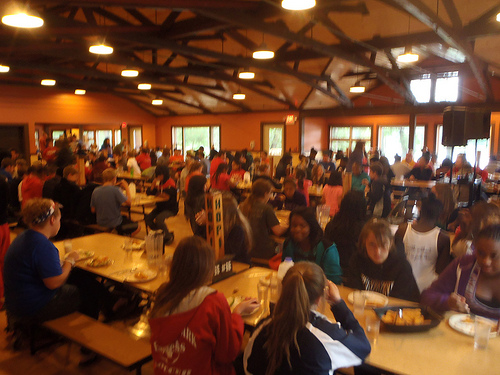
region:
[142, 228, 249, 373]
girl wearing a red hoodie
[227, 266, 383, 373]
girl wearing a blue and white jacket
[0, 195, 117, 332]
boy wearing blue shirt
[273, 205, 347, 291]
girl wearing a teal jacket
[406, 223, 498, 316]
girl wearing a purple jacket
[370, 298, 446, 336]
lunch on the table top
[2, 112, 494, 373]
this is a cafeteria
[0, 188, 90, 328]
boy wearing a headband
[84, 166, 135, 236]
boy wearing a blue shirt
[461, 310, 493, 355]
a cup on the table top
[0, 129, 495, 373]
the cafeteria filled with people eating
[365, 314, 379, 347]
the cup on the table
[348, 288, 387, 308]
the plate on the table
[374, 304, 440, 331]
the big bowl on the table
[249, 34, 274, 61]
the light hanging from the ceiling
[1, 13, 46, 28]
the tree in the distance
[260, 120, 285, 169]
the door to the room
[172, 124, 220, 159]
the window near the door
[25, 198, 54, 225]
the fabric in the girl's hair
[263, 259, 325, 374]
the girl's hair in a ponytail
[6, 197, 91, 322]
a girl in a blue shirt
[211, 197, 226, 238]
the word hop in black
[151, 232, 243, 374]
a girl wearing a red and white hoodie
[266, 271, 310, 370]
a girls long brown pony tail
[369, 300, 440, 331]
food in a big blue bowl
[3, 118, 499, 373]
a bunch of people eating in a caffiteria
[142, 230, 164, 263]
a pitcher of water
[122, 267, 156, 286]
a white plate with food on it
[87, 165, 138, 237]
a young boy eating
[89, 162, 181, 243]
two young boys sitting across from each other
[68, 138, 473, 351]
Students eating lunch in the cafeteria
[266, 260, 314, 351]
The girl hair is in a ponytail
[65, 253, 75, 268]
The girl is wearing a watch.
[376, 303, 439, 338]
Food in a black container on table.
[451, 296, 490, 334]
A white plate with food.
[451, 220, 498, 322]
The girl is eating food.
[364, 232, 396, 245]
The girl is wearing glasses.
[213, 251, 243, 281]
A black item in middle of table.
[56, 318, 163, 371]
A bench at the table.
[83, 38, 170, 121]
Lights on top of the ceiling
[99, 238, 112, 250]
part of a table.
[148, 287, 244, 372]
A red and white jacket.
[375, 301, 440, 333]
A bowl of food.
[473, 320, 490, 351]
A clear drinking glass.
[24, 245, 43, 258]
Part of a blue shirt.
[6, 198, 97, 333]
A woman sitting at a table.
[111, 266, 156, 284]
A plate of food.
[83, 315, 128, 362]
Part of a bench.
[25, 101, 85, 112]
Part of the wall.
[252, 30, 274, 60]
A light hanging from the ceiling.